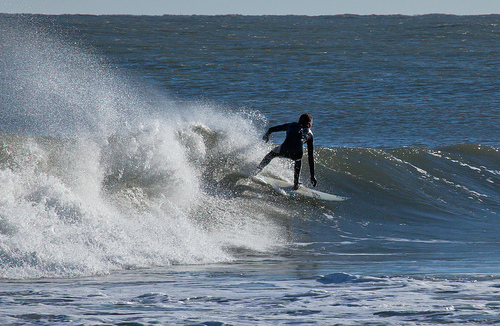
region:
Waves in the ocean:
[6, 128, 276, 280]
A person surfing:
[193, 95, 375, 217]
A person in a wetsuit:
[256, 108, 326, 177]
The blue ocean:
[9, 8, 499, 140]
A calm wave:
[323, 126, 498, 263]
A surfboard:
[230, 163, 342, 210]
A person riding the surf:
[16, 101, 472, 284]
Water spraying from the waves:
[5, 17, 222, 167]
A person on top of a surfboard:
[234, 104, 351, 219]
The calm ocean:
[137, 273, 424, 324]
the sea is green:
[281, 76, 462, 219]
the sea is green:
[235, 80, 385, 237]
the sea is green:
[346, 113, 466, 283]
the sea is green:
[315, 96, 425, 312]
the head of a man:
[296, 108, 316, 128]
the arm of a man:
[303, 130, 318, 176]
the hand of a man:
[306, 170, 320, 189]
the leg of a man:
[289, 155, 307, 186]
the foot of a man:
[291, 177, 307, 193]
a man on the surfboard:
[242, 106, 331, 196]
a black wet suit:
[254, 117, 316, 185]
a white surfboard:
[228, 162, 355, 204]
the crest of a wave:
[1, 127, 499, 174]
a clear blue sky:
[0, 0, 499, 16]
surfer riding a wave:
[188, 74, 388, 254]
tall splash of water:
[26, 25, 259, 264]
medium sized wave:
[51, 69, 465, 250]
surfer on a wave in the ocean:
[14, 11, 484, 301]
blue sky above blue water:
[11, 0, 492, 40]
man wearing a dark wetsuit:
[239, 97, 359, 219]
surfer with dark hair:
[271, 94, 345, 189]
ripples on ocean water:
[139, 262, 391, 316]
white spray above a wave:
[16, 28, 310, 300]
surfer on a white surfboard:
[231, 97, 393, 302]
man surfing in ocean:
[212, 99, 333, 200]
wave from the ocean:
[343, 138, 453, 198]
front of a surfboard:
[308, 185, 355, 210]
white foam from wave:
[38, 194, 183, 234]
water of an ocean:
[313, 35, 465, 92]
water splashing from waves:
[11, 39, 96, 97]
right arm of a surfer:
[256, 121, 283, 143]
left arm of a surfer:
[300, 133, 323, 187]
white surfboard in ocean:
[219, 160, 350, 214]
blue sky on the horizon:
[313, 2, 404, 17]